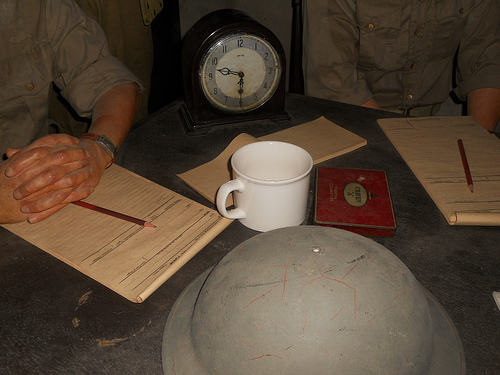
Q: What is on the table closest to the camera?
A: Helmet.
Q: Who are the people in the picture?
A: Soldiers.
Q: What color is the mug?
A: White.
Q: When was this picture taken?
A: 9:30.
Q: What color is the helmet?
A: Gray.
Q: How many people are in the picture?
A: Two.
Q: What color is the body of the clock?
A: Black.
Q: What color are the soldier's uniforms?
A: Olive.